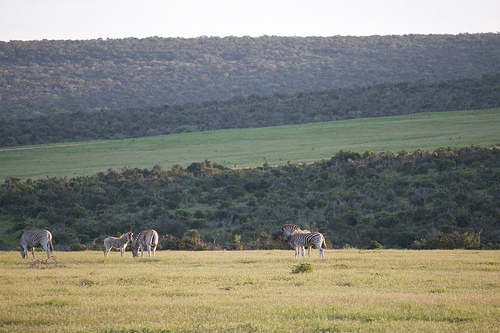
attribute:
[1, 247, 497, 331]
grass — brown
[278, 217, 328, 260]
zebra — striped, black, white, facing left, standing, on end, having fun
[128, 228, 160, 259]
zebra — striped, black, white, eating, in middle, grazing, having fun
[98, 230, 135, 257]
zebra — striped, black, white, standing, in middle, having fun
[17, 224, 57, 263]
zebra — striped, black, white, eating, alone, on end, grazing, having fun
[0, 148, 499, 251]
trees — shrubs, small, green, thick, plants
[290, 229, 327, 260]
stripes — black, white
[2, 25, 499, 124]
hill — distant, outdoor landscape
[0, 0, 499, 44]
sky — white, blue, clear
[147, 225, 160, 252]
butt — brown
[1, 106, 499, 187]
land — sloping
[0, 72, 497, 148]
trees — dark